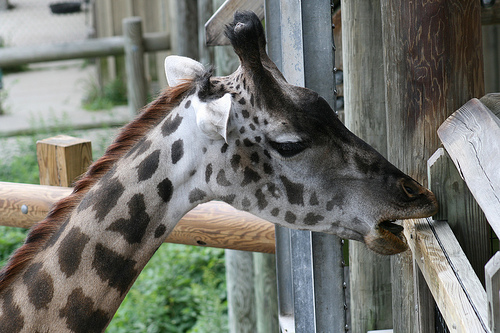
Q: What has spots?
A: A giraffe.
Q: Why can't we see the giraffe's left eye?
A: The giraffe is facing right.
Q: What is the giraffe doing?
A: Chewing.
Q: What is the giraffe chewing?
A: A wood post.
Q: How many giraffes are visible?
A: One.